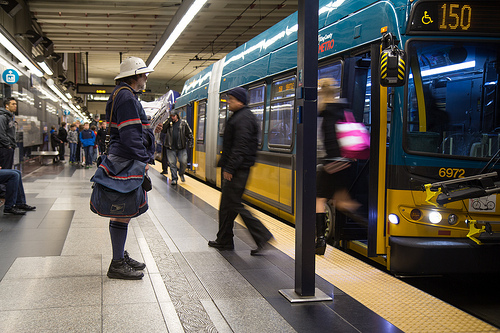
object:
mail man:
[90, 55, 155, 280]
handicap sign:
[421, 11, 434, 25]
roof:
[229, 35, 286, 76]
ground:
[380, 297, 437, 323]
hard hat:
[113, 55, 153, 79]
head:
[114, 57, 153, 89]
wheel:
[312, 196, 340, 249]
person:
[0, 167, 35, 217]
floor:
[164, 276, 299, 331]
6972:
[438, 167, 465, 178]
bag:
[87, 152, 147, 218]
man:
[159, 111, 193, 185]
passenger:
[315, 77, 372, 253]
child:
[67, 123, 78, 166]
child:
[78, 122, 95, 166]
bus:
[174, 0, 496, 277]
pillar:
[292, 0, 319, 300]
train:
[125, 0, 496, 289]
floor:
[19, 279, 89, 315]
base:
[276, 287, 331, 303]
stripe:
[120, 120, 138, 128]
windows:
[268, 100, 291, 149]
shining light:
[428, 210, 442, 223]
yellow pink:
[344, 126, 353, 134]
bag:
[336, 108, 371, 157]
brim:
[115, 68, 154, 81]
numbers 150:
[438, 2, 471, 30]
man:
[207, 88, 281, 256]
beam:
[289, 0, 320, 303]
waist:
[98, 154, 152, 171]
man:
[1, 98, 20, 170]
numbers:
[439, 168, 447, 178]